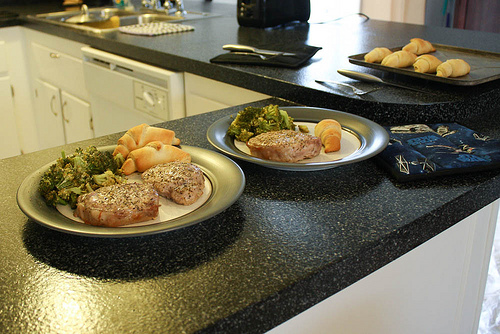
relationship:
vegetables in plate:
[38, 143, 123, 200] [15, 140, 249, 245]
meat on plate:
[72, 178, 161, 227] [10, 94, 302, 249]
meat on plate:
[140, 160, 203, 204] [10, 94, 302, 249]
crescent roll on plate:
[114, 125, 182, 154] [16, 145, 248, 238]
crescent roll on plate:
[114, 143, 191, 167] [16, 145, 248, 238]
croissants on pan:
[362, 36, 468, 78] [347, 35, 498, 87]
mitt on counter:
[360, 95, 497, 201] [0, 3, 497, 330]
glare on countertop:
[15, 251, 104, 327] [0, 0, 497, 331]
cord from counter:
[316, 3, 368, 33] [0, 3, 497, 330]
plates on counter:
[22, 104, 393, 234] [15, 112, 482, 316]